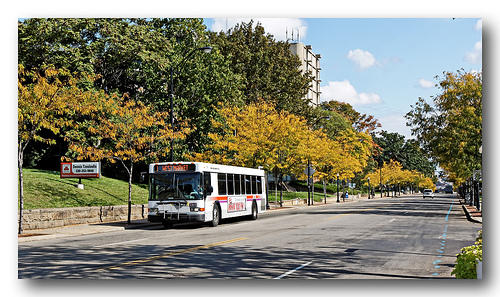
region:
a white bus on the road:
[41, 49, 298, 282]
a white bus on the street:
[85, 93, 247, 284]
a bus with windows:
[94, 82, 274, 289]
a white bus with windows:
[96, 105, 378, 252]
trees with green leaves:
[105, 21, 347, 159]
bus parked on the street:
[119, 107, 371, 269]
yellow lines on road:
[314, 127, 465, 284]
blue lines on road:
[367, 159, 497, 266]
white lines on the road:
[284, 165, 489, 292]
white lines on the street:
[318, 192, 489, 225]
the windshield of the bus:
[146, 167, 209, 204]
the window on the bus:
[213, 168, 230, 198]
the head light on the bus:
[186, 205, 206, 214]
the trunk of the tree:
[116, 162, 139, 223]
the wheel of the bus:
[207, 200, 227, 227]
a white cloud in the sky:
[346, 43, 386, 77]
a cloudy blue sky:
[18, 17, 485, 172]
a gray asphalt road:
[19, 187, 466, 277]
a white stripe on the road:
[273, 250, 316, 280]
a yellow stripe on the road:
[81, 228, 256, 275]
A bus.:
[135, 149, 278, 229]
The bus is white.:
[136, 154, 283, 234]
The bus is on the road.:
[139, 152, 279, 234]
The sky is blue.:
[381, 25, 430, 60]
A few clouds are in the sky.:
[340, 45, 400, 105]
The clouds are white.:
[343, 44, 405, 114]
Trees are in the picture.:
[380, 84, 480, 182]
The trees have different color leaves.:
[373, 95, 482, 169]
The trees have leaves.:
[385, 110, 478, 184]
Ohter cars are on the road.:
[412, 177, 464, 209]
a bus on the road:
[34, 57, 412, 251]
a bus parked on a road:
[85, 90, 317, 292]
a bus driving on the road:
[130, 128, 300, 291]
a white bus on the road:
[99, 102, 358, 236]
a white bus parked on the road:
[102, 120, 396, 288]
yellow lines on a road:
[214, 165, 398, 295]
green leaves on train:
[68, 41, 285, 156]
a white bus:
[87, 99, 321, 285]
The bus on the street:
[143, 154, 270, 227]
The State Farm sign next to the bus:
[53, 153, 104, 183]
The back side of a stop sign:
[302, 159, 317, 187]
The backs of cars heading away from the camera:
[417, 182, 455, 204]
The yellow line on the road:
[63, 191, 418, 281]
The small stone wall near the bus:
[18, 190, 414, 235]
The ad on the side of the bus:
[224, 191, 251, 216]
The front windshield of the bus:
[146, 171, 206, 206]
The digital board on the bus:
[149, 161, 194, 173]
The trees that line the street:
[10, 16, 480, 220]